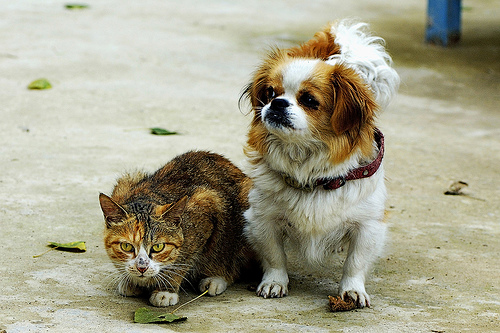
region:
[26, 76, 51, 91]
a green leaf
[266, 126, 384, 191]
a red dog collar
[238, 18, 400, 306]
a small brown and white dog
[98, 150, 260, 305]
a tabby cat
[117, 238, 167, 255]
green cat's eyes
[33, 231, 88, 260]
a green leaf laying on the ground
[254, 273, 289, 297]
right paw on a white dog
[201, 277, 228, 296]
rear left white paw on cat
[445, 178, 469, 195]
dead brown leaf on the ground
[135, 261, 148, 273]
a small pink nose of a cat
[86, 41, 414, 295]
dog and cat on sidewalk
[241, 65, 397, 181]
brown and white dog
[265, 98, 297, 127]
black nose of dog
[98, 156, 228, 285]
brown and white cat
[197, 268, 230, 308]
white paw of cat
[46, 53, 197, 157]
leaves on the ground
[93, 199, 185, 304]
cat looking towards camera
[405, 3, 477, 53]
blue pole behind animals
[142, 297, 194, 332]
green leaf next to cat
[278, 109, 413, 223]
collar around dog's neck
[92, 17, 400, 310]
a dog and a cat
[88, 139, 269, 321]
a brown, gold and white cat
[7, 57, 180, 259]
three green leaves on the ground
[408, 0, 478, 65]
a blue table leg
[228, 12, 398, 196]
a dog with a red collar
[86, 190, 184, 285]
cat with black dots in its nose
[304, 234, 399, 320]
dog paw on a leaf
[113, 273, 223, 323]
one green leaf on the ground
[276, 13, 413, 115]
fluffy brown and white dog tail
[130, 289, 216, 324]
a leaf in front of a cat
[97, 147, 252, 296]
an orange and grey cat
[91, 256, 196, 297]
white whiskers on a cat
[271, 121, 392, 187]
a red collar on a dog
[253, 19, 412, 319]
a brown and white dog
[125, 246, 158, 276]
a white nose on a cat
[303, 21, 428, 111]
a fluffy brown and white tail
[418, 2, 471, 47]
a square blue post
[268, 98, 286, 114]
a black nose on a dog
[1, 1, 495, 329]
old worn concrete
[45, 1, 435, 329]
A cat and dog.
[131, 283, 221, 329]
The leaf is next to the cat.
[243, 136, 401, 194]
The dog is wearing a collar.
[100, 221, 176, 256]
The cat has yellow eyes.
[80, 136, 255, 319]
The cat is multicolored.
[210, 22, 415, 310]
The dog has orange and white patches.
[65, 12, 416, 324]
The dog is bigger than the cat.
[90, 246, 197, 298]
The cat has whiskers.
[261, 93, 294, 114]
The dog has a black nose.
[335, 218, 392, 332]
The front leg of the dog.